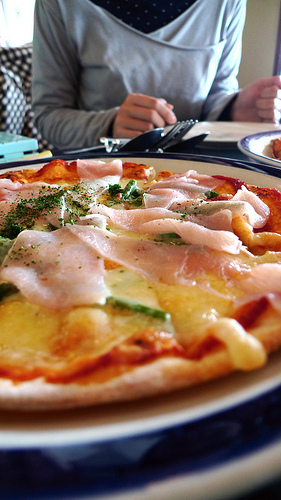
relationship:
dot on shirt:
[130, 5, 138, 9] [130, 3, 180, 20]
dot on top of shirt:
[130, 5, 138, 9] [130, 3, 180, 20]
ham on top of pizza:
[49, 220, 111, 246] [12, 162, 244, 394]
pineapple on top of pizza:
[160, 284, 202, 329] [12, 162, 244, 394]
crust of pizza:
[119, 363, 179, 395] [12, 162, 244, 394]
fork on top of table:
[132, 127, 194, 152] [203, 117, 235, 133]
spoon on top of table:
[124, 137, 164, 150] [203, 117, 235, 133]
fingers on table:
[130, 97, 177, 123] [203, 117, 235, 133]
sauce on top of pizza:
[237, 196, 269, 215] [12, 162, 244, 394]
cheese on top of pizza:
[10, 298, 99, 340] [12, 162, 244, 394]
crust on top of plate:
[119, 363, 179, 395] [149, 139, 201, 165]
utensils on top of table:
[125, 127, 231, 150] [203, 117, 235, 133]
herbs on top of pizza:
[114, 300, 156, 327] [12, 162, 244, 394]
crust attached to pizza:
[119, 363, 179, 395] [12, 162, 244, 394]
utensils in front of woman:
[125, 127, 231, 150] [30, 14, 242, 135]